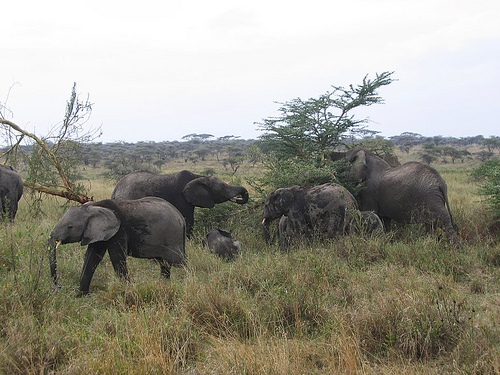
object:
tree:
[0, 80, 95, 206]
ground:
[2, 140, 500, 374]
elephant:
[205, 228, 242, 260]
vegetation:
[278, 242, 497, 374]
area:
[0, 135, 500, 295]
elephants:
[0, 164, 22, 223]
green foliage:
[258, 71, 394, 188]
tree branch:
[344, 118, 370, 127]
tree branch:
[329, 84, 355, 99]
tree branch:
[317, 97, 330, 123]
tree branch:
[274, 97, 304, 113]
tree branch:
[275, 135, 299, 150]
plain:
[0, 138, 500, 375]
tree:
[245, 68, 394, 202]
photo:
[1, 0, 497, 373]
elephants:
[360, 209, 384, 237]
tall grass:
[2, 260, 498, 375]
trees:
[180, 133, 216, 141]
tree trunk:
[23, 180, 91, 201]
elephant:
[323, 149, 466, 244]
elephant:
[261, 183, 360, 244]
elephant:
[111, 169, 248, 240]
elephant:
[47, 197, 189, 299]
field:
[0, 142, 497, 371]